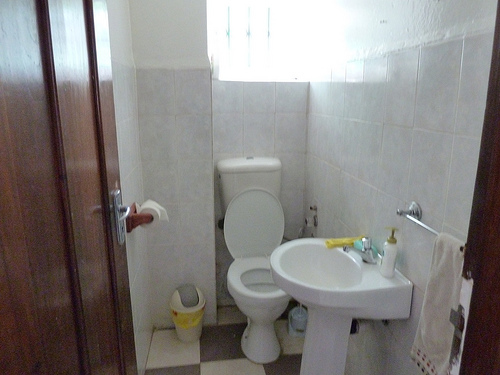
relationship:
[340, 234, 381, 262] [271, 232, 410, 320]
faucet in sink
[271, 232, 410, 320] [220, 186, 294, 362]
sink next to toilet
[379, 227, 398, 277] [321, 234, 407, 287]
bottle on sink edge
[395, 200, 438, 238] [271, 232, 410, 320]
towel bar near sink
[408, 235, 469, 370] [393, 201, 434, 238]
towel hanging from towel bar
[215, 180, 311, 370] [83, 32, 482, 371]
toilet in bathroom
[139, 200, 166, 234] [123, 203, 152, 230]
paper on holder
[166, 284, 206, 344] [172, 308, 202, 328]
can has bag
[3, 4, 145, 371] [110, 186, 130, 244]
door has handle